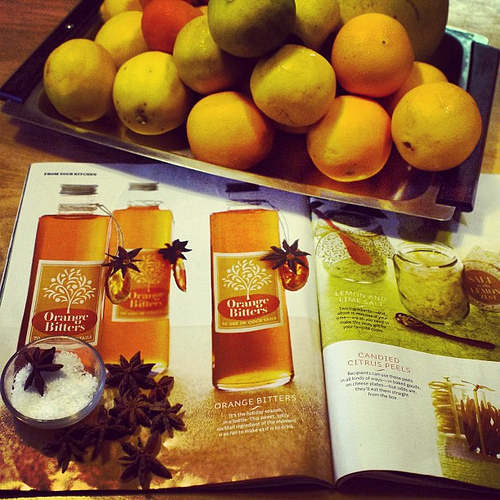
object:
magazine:
[0, 161, 499, 497]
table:
[0, 0, 499, 500]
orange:
[186, 91, 275, 171]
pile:
[42, 0, 481, 183]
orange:
[329, 12, 414, 98]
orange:
[390, 80, 481, 171]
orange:
[305, 93, 392, 182]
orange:
[381, 60, 449, 121]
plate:
[0, 0, 500, 222]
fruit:
[41, 38, 117, 124]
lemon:
[111, 50, 192, 136]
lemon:
[93, 10, 149, 70]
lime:
[206, 0, 297, 59]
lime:
[171, 13, 245, 97]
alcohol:
[209, 207, 296, 394]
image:
[14, 160, 317, 472]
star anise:
[105, 350, 157, 397]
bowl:
[0, 333, 107, 430]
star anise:
[117, 430, 173, 493]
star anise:
[101, 245, 144, 279]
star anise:
[23, 346, 64, 397]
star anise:
[259, 238, 312, 276]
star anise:
[108, 386, 153, 435]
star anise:
[149, 396, 188, 438]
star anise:
[42, 423, 85, 474]